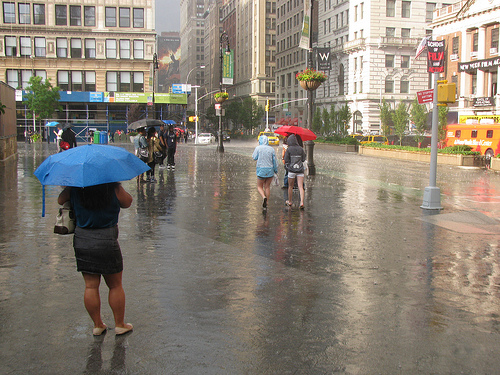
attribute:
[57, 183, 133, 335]
woman — standing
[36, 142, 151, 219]
umbrella — open, blue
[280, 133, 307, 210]
girl — walking, pedestrian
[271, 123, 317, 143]
umbrella — open, red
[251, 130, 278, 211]
girl — walking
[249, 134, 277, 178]
jacket — hoodie, blue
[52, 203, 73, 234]
handbag — brown, white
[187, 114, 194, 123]
light — yellow, crosswalk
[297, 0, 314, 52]
banner — white, green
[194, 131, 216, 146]
car — white, turning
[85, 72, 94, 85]
shade — white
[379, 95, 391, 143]
tree — young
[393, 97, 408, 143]
tree — young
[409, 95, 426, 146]
tree — young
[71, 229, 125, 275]
skirt — short, black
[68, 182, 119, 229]
shirt — navy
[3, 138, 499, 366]
sidewalk — concrete, wet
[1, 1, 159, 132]
building — brick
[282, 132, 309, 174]
sweatshirt — hoodie, hooded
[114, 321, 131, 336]
shoe — flat, beige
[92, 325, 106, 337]
shoe — flat, beige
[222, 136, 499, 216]
street — wet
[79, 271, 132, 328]
skin — dark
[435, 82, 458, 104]
light — yellow, crosswalk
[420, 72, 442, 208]
pole — gray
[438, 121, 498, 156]
truck — orange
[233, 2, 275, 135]
building — tall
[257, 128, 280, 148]
car — yellow